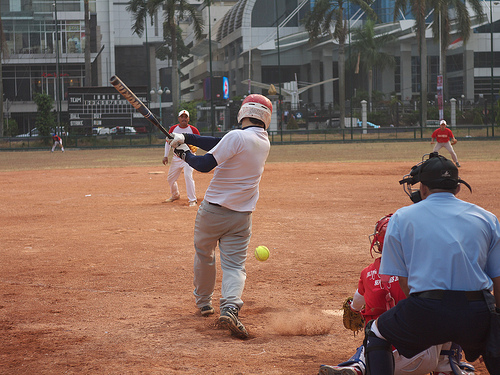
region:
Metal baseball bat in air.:
[109, 71, 180, 141]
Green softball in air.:
[256, 245, 270, 262]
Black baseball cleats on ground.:
[216, 307, 249, 339]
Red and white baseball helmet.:
[237, 92, 274, 132]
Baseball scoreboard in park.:
[69, 86, 151, 130]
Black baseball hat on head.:
[413, 157, 460, 192]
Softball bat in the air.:
[112, 74, 179, 141]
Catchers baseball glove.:
[342, 296, 364, 343]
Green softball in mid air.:
[255, 245, 270, 259]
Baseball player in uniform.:
[433, 121, 464, 167]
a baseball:
[254, 242, 283, 265]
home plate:
[319, 299, 341, 318]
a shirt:
[402, 210, 486, 283]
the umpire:
[398, 168, 498, 340]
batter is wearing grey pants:
[197, 213, 242, 252]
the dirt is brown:
[54, 218, 169, 301]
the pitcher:
[157, 159, 184, 193]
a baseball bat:
[105, 72, 162, 129]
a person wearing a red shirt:
[425, 120, 462, 146]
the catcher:
[351, 277, 384, 306]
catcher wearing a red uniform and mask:
[353, 213, 449, 370]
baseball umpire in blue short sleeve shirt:
[374, 153, 499, 374]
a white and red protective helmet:
[235, 90, 274, 124]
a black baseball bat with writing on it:
[108, 71, 175, 145]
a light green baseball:
[252, 243, 271, 263]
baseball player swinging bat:
[107, 71, 272, 342]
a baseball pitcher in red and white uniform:
[162, 108, 199, 203]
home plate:
[322, 303, 346, 323]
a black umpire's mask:
[399, 150, 461, 200]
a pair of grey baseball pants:
[187, 203, 244, 308]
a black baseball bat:
[108, 73, 170, 140]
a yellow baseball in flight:
[250, 244, 271, 264]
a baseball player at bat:
[106, 68, 279, 339]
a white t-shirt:
[206, 123, 270, 210]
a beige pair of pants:
[192, 198, 252, 307]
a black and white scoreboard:
[65, 85, 150, 128]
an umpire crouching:
[364, 155, 497, 372]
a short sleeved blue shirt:
[378, 198, 498, 294]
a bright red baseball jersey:
[430, 125, 453, 143]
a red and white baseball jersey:
[167, 123, 198, 150]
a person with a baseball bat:
[106, 71, 274, 340]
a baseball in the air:
[252, 245, 270, 261]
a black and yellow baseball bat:
[108, 73, 173, 141]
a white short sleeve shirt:
[200, 128, 270, 211]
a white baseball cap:
[177, 109, 189, 118]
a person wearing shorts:
[363, 152, 499, 374]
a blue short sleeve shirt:
[377, 190, 499, 292]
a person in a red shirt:
[426, 118, 462, 169]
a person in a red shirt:
[48, 130, 65, 151]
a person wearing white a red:
[163, 108, 195, 206]